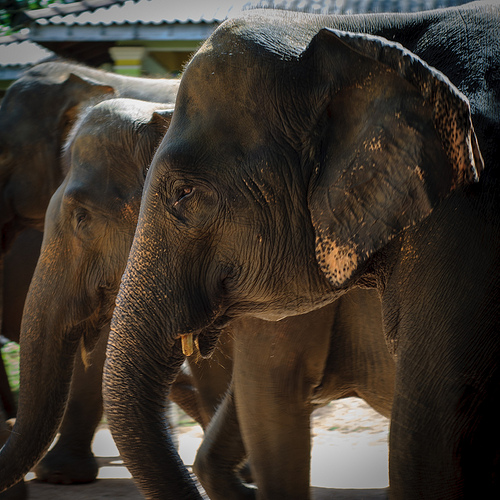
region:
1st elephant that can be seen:
[104, 4, 499, 498]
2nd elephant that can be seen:
[0, 80, 396, 498]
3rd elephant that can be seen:
[3, 52, 182, 326]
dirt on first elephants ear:
[315, 232, 357, 288]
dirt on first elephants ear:
[425, 77, 482, 188]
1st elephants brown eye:
[168, 177, 206, 209]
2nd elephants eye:
[63, 198, 95, 232]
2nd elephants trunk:
[1, 240, 81, 494]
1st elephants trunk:
[96, 226, 216, 498]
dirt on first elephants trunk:
[97, 219, 172, 484]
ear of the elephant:
[260, 45, 485, 242]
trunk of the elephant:
[105, 311, 210, 493]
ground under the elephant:
[325, 441, 366, 486]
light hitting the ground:
[325, 426, 370, 481]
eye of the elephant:
[142, 152, 229, 237]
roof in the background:
[96, 1, 186, 26]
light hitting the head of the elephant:
[241, 10, 312, 48]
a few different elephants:
[7, 63, 320, 270]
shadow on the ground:
[99, 466, 122, 498]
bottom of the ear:
[305, 228, 372, 298]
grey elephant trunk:
[99, 213, 204, 498]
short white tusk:
[175, 333, 200, 359]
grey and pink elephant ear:
[291, 22, 488, 286]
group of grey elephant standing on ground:
[1, 0, 496, 492]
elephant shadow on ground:
[82, 437, 198, 497]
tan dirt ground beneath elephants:
[319, 409, 381, 481]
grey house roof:
[5, 1, 463, 41]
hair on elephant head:
[56, 95, 111, 156]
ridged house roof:
[39, 9, 221, 31]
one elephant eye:
[162, 172, 206, 214]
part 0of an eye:
[164, 167, 209, 210]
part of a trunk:
[116, 366, 151, 421]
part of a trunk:
[121, 378, 174, 460]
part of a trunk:
[211, 405, 242, 451]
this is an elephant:
[126, 5, 491, 485]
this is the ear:
[295, 36, 468, 253]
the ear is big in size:
[290, 24, 470, 252]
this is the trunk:
[108, 337, 188, 499]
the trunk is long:
[96, 349, 172, 496]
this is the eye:
[177, 179, 199, 201]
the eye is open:
[174, 177, 198, 203]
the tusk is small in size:
[180, 330, 193, 354]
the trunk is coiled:
[0, 343, 80, 480]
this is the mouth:
[198, 311, 232, 358]